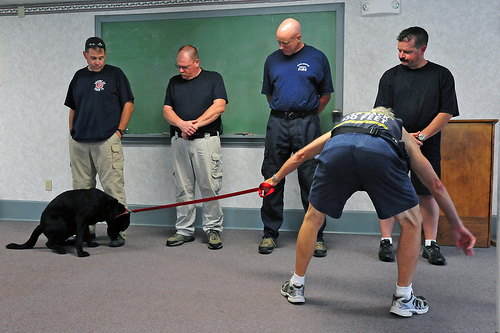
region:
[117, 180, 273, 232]
the red lesh of the dog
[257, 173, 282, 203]
the hand holding onto the leash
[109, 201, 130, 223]
the red collar of the dog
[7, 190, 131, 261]
the black dog sitting on the carpet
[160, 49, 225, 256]
the man standing agianst the chalk board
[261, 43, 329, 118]
the blue tee shirt of the man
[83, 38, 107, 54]
sunglasses on the mans head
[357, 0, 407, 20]
light on the wall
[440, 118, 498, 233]
a wooden podium behind the man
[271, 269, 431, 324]
the white socks and tennis shoes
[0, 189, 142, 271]
black dog on floor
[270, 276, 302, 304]
shoe of the person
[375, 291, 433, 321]
shoe of the person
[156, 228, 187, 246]
shoe of the person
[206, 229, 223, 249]
shoe of the person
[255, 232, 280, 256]
shoe of the person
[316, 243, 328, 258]
shoe of the person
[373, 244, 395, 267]
shoe of the person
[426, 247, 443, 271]
shoe of the person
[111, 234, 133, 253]
shoe of the person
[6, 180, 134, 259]
a stubborn dog trying to sit down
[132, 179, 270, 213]
the leash attached to the collar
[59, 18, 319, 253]
the men standing by the chalkboard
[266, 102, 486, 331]
the person holding the leash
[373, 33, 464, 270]
the man standing by the podium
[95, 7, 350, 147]
the chalkboard behind the men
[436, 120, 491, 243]
the podium by the wall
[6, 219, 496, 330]
the floor the people are standing on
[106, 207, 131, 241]
the sad looking dog face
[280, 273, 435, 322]
the shoes the man is wearing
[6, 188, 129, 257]
a sitting black lab retriever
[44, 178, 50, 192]
a beige electrical outlet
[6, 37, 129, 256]
a white man standing and watching a black dog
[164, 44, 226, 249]
a standing man in a black shirt and khaki pants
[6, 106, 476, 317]
a man trying to train a dog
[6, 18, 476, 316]
men watching and training a dog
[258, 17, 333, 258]
a man standing in the back of a room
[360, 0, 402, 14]
a white emergency light box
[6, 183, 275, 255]
a black dog on a red leash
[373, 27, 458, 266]
a man in the back of the room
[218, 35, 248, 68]
the chalkboard is green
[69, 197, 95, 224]
the dog is black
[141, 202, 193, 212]
the leash is red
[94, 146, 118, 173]
the pants are dark gray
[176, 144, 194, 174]
the pants are light gray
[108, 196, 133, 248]
the dog is pulling on the leash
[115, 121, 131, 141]
the man has a watch on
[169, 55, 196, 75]
the man is wearing glasses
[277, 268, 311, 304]
the shoes are silver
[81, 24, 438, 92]
the men are watching the dog